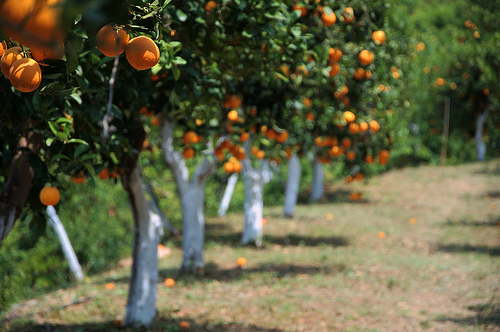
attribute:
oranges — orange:
[6, 24, 180, 114]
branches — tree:
[86, 62, 131, 140]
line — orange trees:
[4, 0, 499, 325]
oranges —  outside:
[1, 11, 426, 213]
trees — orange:
[216, 60, 318, 162]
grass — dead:
[270, 242, 400, 272]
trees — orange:
[2, 6, 482, 198]